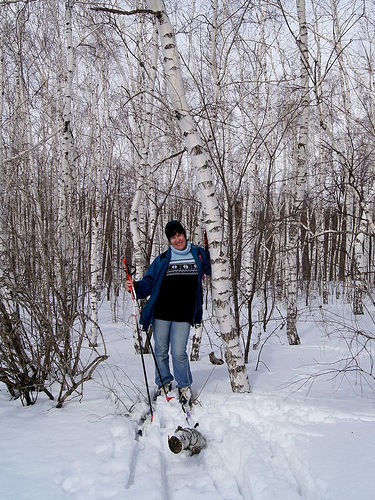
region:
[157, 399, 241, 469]
split tree protruding from snow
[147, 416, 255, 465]
light blue foot pad for washing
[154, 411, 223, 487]
light blue foot pad for washing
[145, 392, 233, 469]
light blue foot pad for washing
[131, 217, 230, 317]
The woman is smiling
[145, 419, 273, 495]
a log is sticking out of the snow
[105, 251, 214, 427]
The woman is holding ski poles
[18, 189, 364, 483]
The woman is standing in snow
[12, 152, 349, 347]
Trees are surrounding the woman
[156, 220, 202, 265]
The woman's hair is black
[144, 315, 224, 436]
The woman is wearing blue jeans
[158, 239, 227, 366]
The woman has on a turtle neck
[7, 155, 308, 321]
The trees have no leaves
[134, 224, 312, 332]
The woman's arm is on a tree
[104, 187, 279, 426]
"The woman is outside"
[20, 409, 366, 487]
"Snow is on the ground"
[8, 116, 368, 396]
"A picture of a wooded area"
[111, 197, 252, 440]
"The lady is wearing skis"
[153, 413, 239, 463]
"There is a log on the ground"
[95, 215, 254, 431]
"The lady is wearing a blue coat"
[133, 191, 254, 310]
"She has dark hair"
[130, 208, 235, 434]
"She is wearing is a sweater"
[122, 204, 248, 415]
"The woman is dressed in mostly blue clothing"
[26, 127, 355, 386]
"The trees have no leaves"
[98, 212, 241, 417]
WOMAN IN BLUE HOLDING SKIS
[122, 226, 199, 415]
this is a woman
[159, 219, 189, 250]
the woman is smiling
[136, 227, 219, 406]
the woman is standing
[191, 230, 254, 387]
the woman is holding a tree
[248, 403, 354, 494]
this is the ground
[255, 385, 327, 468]
this is the snow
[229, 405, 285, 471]
the snow is white in color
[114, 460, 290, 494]
there are tracks on the snow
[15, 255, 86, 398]
this is a shrub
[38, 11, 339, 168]
these are several trees